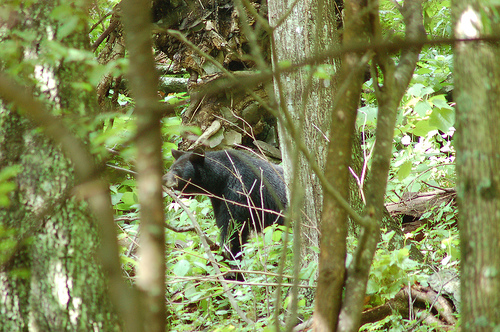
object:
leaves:
[113, 202, 133, 210]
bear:
[161, 144, 288, 281]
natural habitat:
[0, 0, 499, 331]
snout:
[161, 172, 176, 189]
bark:
[450, 0, 498, 331]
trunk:
[448, 0, 499, 331]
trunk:
[0, 0, 125, 331]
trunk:
[267, 0, 420, 308]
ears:
[187, 153, 205, 166]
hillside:
[96, 0, 284, 164]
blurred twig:
[0, 35, 499, 268]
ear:
[170, 148, 183, 160]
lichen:
[323, 99, 328, 102]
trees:
[0, 0, 121, 330]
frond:
[428, 107, 452, 132]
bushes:
[0, 0, 499, 331]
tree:
[450, 0, 500, 330]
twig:
[253, 0, 296, 37]